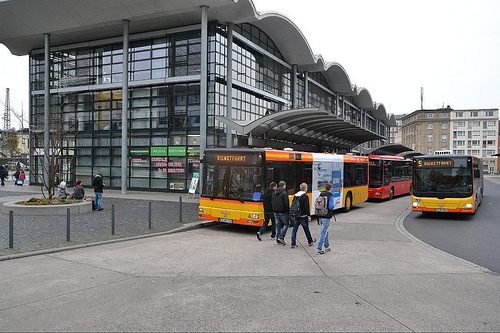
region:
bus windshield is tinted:
[413, 166, 475, 197]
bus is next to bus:
[412, 156, 487, 217]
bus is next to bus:
[198, 149, 369, 230]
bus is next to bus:
[365, 153, 413, 202]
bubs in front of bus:
[196, 150, 372, 230]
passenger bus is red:
[368, 154, 416, 199]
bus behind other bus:
[369, 153, 414, 199]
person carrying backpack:
[315, 182, 339, 252]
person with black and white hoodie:
[287, 181, 319, 248]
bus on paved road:
[402, 159, 498, 281]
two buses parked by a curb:
[194, 142, 414, 232]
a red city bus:
[367, 150, 413, 202]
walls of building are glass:
[21, 20, 396, 197]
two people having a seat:
[52, 177, 87, 207]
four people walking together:
[255, 178, 344, 258]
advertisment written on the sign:
[147, 153, 189, 175]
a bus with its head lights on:
[407, 151, 487, 219]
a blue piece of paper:
[250, 190, 264, 204]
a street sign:
[185, 168, 200, 200]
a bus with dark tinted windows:
[367, 148, 414, 199]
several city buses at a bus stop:
[190, 141, 493, 260]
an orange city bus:
[408, 149, 492, 226]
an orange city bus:
[198, 143, 371, 224]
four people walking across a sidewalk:
[249, 178, 383, 307]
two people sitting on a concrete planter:
[53, 173, 88, 205]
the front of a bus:
[202, 147, 264, 229]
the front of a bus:
[413, 156, 468, 212]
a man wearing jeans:
[315, 179, 343, 258]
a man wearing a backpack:
[313, 182, 339, 255]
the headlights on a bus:
[411, 197, 473, 212]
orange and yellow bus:
[408, 150, 480, 218]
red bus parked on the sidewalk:
[364, 150, 411, 201]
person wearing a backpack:
[313, 183, 338, 255]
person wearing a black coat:
[270, 180, 290, 245]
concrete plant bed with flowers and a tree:
[6, 188, 96, 219]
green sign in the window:
[150, 145, 185, 155]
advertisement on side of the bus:
[311, 150, 342, 213]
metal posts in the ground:
[3, 194, 198, 252]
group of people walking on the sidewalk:
[257, 180, 334, 255]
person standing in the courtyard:
[92, 168, 109, 211]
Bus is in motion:
[183, 118, 488, 242]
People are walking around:
[252, 176, 349, 260]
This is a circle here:
[3, 180, 98, 219]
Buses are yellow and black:
[198, 129, 490, 232]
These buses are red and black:
[368, 151, 415, 213]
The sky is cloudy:
[316, 8, 483, 89]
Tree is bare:
[7, 85, 79, 204]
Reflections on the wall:
[29, 37, 202, 194]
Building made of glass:
[23, 46, 215, 197]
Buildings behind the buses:
[390, 98, 498, 179]